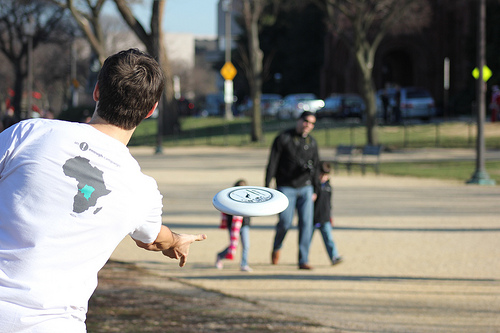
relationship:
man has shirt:
[3, 43, 192, 332] [2, 121, 129, 320]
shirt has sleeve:
[2, 121, 129, 320] [142, 188, 156, 244]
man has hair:
[3, 43, 192, 332] [101, 58, 148, 119]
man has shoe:
[269, 112, 311, 270] [273, 251, 279, 265]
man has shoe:
[269, 112, 311, 270] [299, 260, 315, 270]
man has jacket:
[269, 112, 311, 270] [281, 138, 314, 187]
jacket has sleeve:
[281, 138, 314, 187] [262, 139, 282, 180]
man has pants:
[269, 112, 311, 270] [279, 186, 310, 257]